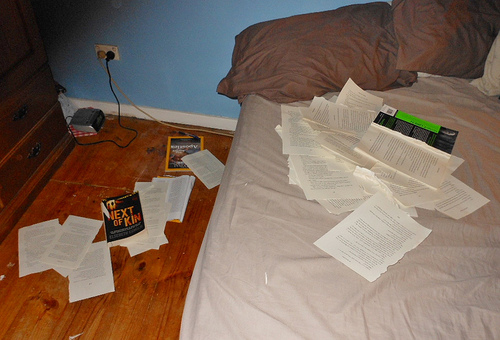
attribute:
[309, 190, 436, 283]
paper — white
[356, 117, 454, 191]
paper — white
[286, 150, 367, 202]
paper — white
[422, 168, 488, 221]
paper — white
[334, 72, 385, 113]
paper — white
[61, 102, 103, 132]
alarm clock — silver, black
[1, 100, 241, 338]
floor — wood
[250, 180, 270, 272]
sheet — tan-colored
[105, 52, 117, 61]
plug — black and yellow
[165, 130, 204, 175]
magazine — yellow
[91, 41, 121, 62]
socket — white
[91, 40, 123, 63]
outlet — white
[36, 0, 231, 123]
wall — blue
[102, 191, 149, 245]
book — black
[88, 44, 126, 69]
socket — white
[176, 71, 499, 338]
sheet — white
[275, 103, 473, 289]
paper — white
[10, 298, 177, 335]
floor — wooden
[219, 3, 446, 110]
cover — wrinkled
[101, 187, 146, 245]
cover — black